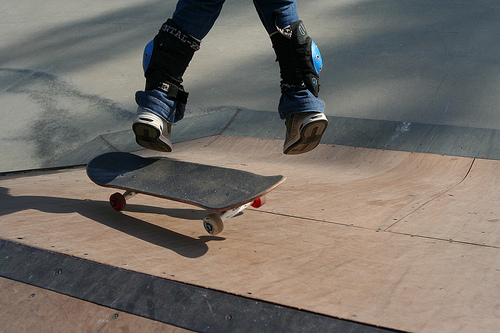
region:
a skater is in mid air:
[116, 3, 328, 154]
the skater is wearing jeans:
[140, 1, 325, 123]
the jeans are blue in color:
[135, 3, 328, 118]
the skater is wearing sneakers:
[131, 107, 330, 157]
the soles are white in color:
[135, 110, 327, 155]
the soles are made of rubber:
[130, 111, 327, 155]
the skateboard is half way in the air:
[87, 146, 276, 235]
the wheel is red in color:
[251, 192, 266, 211]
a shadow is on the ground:
[2, 183, 253, 260]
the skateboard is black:
[80, 128, 318, 242]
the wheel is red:
[101, 187, 147, 215]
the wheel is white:
[203, 209, 227, 237]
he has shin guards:
[118, 25, 329, 85]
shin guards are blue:
[130, 13, 336, 86]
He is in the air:
[112, 70, 334, 194]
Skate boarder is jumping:
[94, 26, 344, 232]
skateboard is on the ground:
[52, 142, 301, 240]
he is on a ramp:
[75, 88, 440, 325]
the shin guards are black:
[285, 28, 318, 74]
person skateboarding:
[68, 0, 381, 262]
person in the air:
[102, 2, 343, 165]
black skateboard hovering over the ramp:
[77, 142, 299, 245]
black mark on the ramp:
[375, 261, 417, 324]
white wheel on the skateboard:
[201, 215, 223, 233]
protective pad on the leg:
[268, 20, 340, 100]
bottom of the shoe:
[281, 120, 331, 160]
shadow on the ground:
[0, 180, 250, 265]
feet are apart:
[122, 4, 339, 174]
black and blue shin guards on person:
[124, 18, 342, 107]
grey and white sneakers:
[118, 85, 336, 164]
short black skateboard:
[70, 140, 299, 237]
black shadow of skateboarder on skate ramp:
[1, 170, 250, 283]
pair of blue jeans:
[134, 1, 328, 121]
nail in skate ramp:
[20, 285, 45, 307]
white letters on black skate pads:
[161, 21, 202, 54]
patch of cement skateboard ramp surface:
[33, 18, 120, 60]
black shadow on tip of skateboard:
[79, 135, 164, 189]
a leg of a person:
[98, 0, 235, 165]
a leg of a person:
[244, 13, 339, 165]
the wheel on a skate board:
[164, 195, 231, 246]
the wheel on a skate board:
[90, 189, 141, 230]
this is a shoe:
[268, 103, 346, 165]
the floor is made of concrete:
[231, 193, 392, 307]